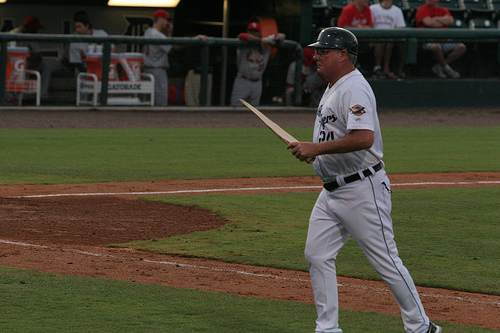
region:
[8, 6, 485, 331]
baseball player on the ball field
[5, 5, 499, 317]
baseball player at a baseball stadium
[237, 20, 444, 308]
baseball player wearing sunglasses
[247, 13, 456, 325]
baseball player wearing a black helmet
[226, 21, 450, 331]
baseball player carrying a sign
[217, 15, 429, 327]
baseball player wearing a white and black uniform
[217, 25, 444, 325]
baseball player walking on the baseball field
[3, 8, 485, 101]
baseball player in the background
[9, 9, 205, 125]
orange Gatorade containers in the background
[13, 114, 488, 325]
grass and soil turf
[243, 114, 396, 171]
a person holding a piece of wood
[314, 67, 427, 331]
a white baseball uniform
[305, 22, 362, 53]
a player wearing a batter's helmet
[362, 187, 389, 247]
a black stripe on white pants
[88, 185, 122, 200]
white chalk on a baseball diamond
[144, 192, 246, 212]
a patch of green grass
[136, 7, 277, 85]
players in a dugout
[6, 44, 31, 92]
a orange and grey drink cooler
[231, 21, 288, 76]
a player leaning on a rail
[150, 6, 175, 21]
a red baseball cap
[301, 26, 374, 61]
the man is wearing helmet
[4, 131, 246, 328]
this is baseball pitch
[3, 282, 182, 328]
baseball pitch is green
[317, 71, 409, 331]
the baseball player is wearing a white costume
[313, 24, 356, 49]
the helmet is black in color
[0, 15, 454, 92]
the spectators are watching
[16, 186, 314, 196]
a white strip is drawn on the pitch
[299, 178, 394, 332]
the players t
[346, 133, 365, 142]
the players skin color is white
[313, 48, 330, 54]
the man is wearing googles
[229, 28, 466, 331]
a baseball player is holding a broken bat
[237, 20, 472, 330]
a man is holding a wooden stake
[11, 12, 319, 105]
spectators watch a baseball game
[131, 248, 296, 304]
red clay dirt between to grassy areas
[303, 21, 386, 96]
a man is wearing a dark blue helmet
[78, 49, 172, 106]
two orange coolers holding gatorade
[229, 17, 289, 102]
a baseball player leans on a metal bar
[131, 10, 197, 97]
a man wearing a red hat is looking at the crowd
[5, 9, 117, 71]
two men are talking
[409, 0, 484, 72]
a spectator wearing a red shirts has his arms folded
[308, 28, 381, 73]
helmet is black in color.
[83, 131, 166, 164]
grass is green in color.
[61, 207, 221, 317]
white lines are drawn in the ground.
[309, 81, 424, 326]
man is wearing white dress.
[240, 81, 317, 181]
man is holding a bat in his hand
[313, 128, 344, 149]
24 is written in his shirt.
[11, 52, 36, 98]
trash can is orange in color.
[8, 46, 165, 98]
3 cans are there.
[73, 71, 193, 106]
trolley is white in color.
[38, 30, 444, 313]
daytime picture.